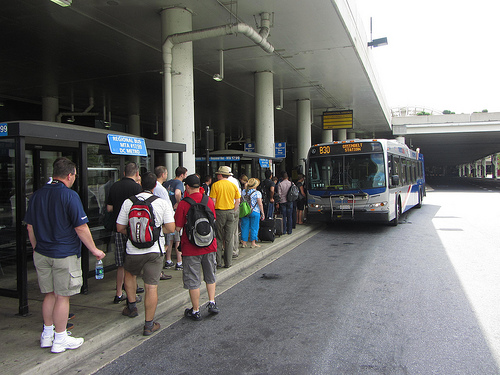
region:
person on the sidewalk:
[43, 160, 98, 346]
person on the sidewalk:
[126, 183, 177, 334]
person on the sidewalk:
[180, 176, 225, 327]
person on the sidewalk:
[205, 163, 250, 270]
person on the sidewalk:
[147, 163, 189, 268]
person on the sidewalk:
[231, 172, 266, 242]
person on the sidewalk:
[273, 171, 295, 243]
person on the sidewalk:
[130, 155, 140, 220]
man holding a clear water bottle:
[24, 156, 104, 353]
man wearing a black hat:
[174, 173, 216, 318]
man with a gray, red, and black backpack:
[119, 169, 173, 334]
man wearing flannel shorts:
[101, 163, 146, 305]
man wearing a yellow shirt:
[211, 165, 240, 266]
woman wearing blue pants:
[236, 176, 264, 249]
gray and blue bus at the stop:
[305, 137, 423, 229]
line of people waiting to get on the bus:
[21, 166, 309, 355]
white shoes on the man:
[36, 324, 84, 354]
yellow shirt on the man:
[211, 178, 238, 210]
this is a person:
[0, 133, 132, 360]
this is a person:
[104, 171, 196, 339]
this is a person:
[168, 162, 238, 324]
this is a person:
[206, 164, 252, 265]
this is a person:
[240, 165, 276, 253]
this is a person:
[253, 159, 296, 236]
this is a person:
[271, 157, 309, 229]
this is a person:
[161, 161, 213, 281]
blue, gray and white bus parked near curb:
[303, 133, 433, 231]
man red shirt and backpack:
[172, 170, 234, 319]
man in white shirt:
[117, 165, 176, 332]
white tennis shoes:
[33, 320, 97, 362]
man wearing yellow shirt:
[208, 162, 243, 270]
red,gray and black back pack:
[124, 189, 167, 256]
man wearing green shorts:
[23, 156, 118, 356]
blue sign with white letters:
[94, 133, 158, 170]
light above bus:
[361, 28, 402, 62]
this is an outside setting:
[24, 21, 434, 332]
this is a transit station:
[59, 47, 451, 274]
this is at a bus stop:
[143, 86, 416, 266]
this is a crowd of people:
[37, 127, 248, 329]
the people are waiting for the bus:
[52, 125, 282, 268]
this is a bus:
[290, 132, 477, 267]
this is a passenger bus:
[305, 124, 462, 252]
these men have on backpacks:
[115, 187, 305, 276]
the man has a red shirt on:
[169, 196, 236, 276]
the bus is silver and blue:
[302, 122, 448, 277]